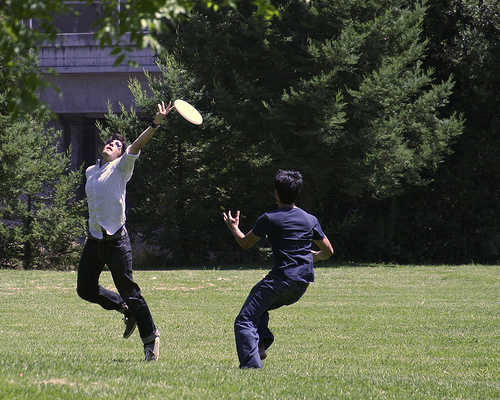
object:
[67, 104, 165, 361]
man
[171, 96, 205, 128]
frisbee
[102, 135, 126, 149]
sunglasses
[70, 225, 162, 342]
pants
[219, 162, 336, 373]
man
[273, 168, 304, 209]
black hair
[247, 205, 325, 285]
black shirt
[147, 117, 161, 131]
black watch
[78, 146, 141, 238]
shirt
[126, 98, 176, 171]
arm extended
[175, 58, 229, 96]
air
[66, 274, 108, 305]
bent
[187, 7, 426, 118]
trees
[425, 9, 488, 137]
background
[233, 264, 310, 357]
jeans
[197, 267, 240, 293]
foreground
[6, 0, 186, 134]
building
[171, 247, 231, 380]
field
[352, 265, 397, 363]
grass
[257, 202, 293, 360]
blue clothes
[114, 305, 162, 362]
brown shoes